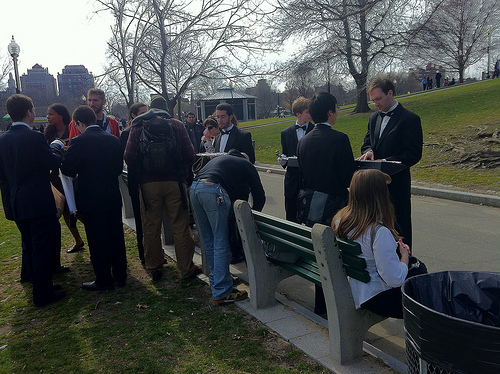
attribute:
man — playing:
[356, 79, 423, 277]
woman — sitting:
[329, 168, 431, 314]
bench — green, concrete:
[233, 207, 387, 313]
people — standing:
[7, 89, 142, 303]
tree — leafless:
[264, 3, 402, 126]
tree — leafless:
[97, 0, 172, 133]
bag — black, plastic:
[404, 270, 498, 344]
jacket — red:
[69, 110, 124, 154]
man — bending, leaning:
[193, 146, 268, 311]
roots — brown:
[446, 132, 497, 179]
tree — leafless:
[402, 2, 499, 90]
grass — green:
[239, 78, 498, 180]